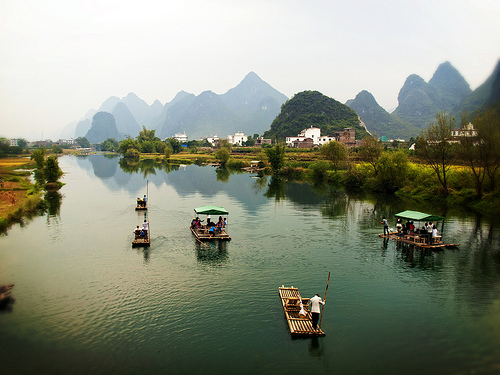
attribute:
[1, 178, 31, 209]
dirt — brown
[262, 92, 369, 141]
mountain — large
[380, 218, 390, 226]
shirt — blue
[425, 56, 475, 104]
mountain peak — mountain 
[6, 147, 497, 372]
water — green, wavy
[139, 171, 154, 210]
stick — wood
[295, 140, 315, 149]
house — a group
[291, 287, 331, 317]
shirt — white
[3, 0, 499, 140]
gray sky — foggy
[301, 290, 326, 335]
man — in the back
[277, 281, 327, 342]
raft — his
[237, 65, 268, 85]
peak — mountain 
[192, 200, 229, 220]
covering — green